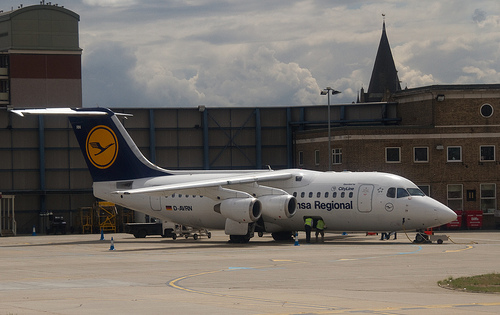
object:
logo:
[84, 124, 119, 170]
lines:
[167, 239, 498, 313]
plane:
[8, 104, 460, 243]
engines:
[212, 196, 262, 221]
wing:
[110, 172, 293, 196]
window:
[386, 187, 397, 196]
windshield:
[406, 186, 429, 197]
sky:
[1, 1, 500, 108]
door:
[356, 182, 374, 213]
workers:
[304, 217, 314, 242]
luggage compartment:
[301, 215, 328, 230]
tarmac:
[1, 230, 500, 313]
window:
[382, 148, 398, 161]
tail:
[8, 104, 177, 180]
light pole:
[323, 93, 334, 172]